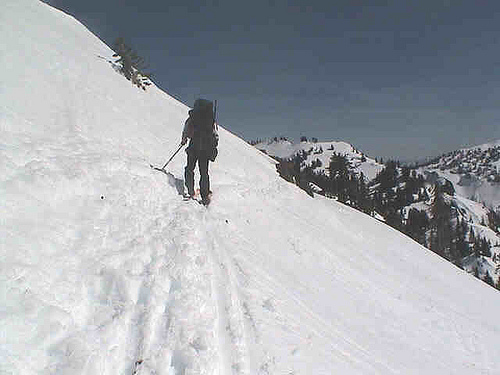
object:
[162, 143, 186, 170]
ski pole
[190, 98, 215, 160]
backpack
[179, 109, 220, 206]
man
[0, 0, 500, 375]
snow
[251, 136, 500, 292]
mountain top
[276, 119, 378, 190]
sign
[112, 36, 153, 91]
branch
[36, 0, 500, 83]
sky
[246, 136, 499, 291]
trees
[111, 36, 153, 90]
tree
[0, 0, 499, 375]
mountainside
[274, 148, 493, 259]
pines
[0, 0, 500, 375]
hill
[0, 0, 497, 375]
ground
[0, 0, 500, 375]
mountain